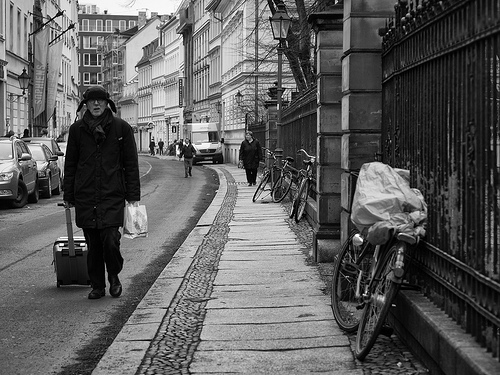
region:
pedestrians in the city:
[3, 3, 495, 369]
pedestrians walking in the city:
[22, 14, 480, 360]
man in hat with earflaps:
[48, 83, 155, 303]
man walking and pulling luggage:
[46, 83, 159, 306]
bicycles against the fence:
[253, 148, 437, 371]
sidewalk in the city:
[173, 174, 320, 373]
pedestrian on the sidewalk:
[231, 124, 286, 238]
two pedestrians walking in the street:
[36, 80, 223, 324]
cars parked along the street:
[1, 82, 62, 261]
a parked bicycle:
[326, 166, 428, 356]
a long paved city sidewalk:
[98, 146, 407, 372]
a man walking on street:
[52, 82, 148, 304]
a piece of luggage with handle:
[52, 201, 90, 291]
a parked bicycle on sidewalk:
[252, 145, 292, 205]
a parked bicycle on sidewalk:
[287, 145, 313, 221]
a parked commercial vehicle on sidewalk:
[182, 120, 220, 165]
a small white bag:
[121, 200, 147, 238]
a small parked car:
[0, 135, 36, 205]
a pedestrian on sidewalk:
[238, 128, 263, 186]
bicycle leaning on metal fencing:
[303, 146, 430, 368]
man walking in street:
[44, 78, 152, 316]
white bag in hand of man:
[113, 195, 163, 250]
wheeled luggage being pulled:
[38, 178, 105, 309]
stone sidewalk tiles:
[223, 257, 325, 374]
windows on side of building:
[80, 15, 105, 86]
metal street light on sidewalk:
[265, 0, 292, 151]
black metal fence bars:
[373, 13, 499, 158]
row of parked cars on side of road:
[0, 133, 69, 203]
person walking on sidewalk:
[230, 125, 262, 188]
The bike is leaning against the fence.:
[248, 0, 499, 372]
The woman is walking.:
[214, 99, 294, 216]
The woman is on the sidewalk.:
[156, 109, 456, 374]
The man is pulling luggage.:
[28, 65, 225, 352]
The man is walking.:
[23, 71, 194, 311]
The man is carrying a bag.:
[21, 45, 193, 347]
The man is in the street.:
[41, 48, 218, 333]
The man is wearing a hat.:
[14, 53, 189, 328]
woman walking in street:
[50, 80, 151, 320]